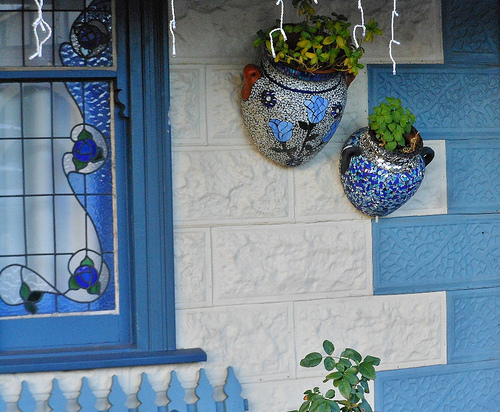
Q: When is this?
A: Daytime.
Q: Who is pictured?
A: No one is pictured.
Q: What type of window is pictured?
A: Stained glass.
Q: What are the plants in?
A: Planters.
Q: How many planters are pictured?
A: Two.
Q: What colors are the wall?
A: Blue and white.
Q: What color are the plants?
A: Green.